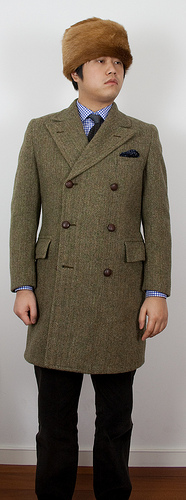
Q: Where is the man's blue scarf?
A: In his chest pocket.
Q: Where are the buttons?
A: On the front of the man's coat.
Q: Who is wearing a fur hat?
A: The man in the blue tie.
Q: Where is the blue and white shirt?
A: Under the man's coat.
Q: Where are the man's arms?
A: Resting at his side.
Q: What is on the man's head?
A: A hat.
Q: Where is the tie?
A: Around the man's neck.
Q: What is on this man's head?
A: A hat.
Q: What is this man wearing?
A: A coat.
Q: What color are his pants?
A: Black.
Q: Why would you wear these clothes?
A: Colder weather.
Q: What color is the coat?
A: Brown.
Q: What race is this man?
A: Asian.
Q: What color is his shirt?
A: Blue.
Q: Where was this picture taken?
A: In front of a wall.